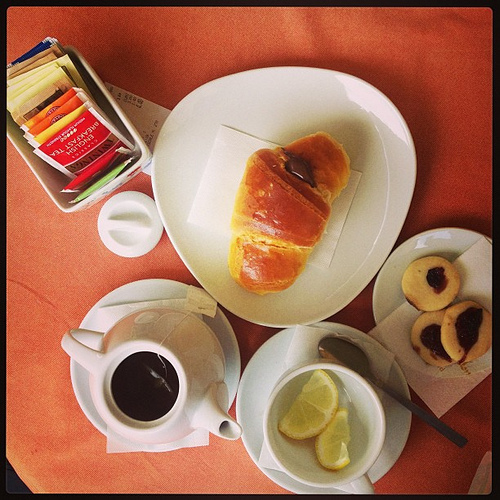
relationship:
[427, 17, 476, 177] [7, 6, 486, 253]
table cloth on table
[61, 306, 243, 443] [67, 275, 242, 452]
kettle on plate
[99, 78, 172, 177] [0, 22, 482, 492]
bill on table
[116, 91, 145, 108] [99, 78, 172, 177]
black lettering on bill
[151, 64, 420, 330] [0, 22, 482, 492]
plate on table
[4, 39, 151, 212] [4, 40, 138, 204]
container holding bags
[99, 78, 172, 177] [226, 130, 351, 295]
bill on crossant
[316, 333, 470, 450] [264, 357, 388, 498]
metal spoon on cup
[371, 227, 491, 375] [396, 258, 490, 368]
plate on cookies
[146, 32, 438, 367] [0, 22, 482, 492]
plate on table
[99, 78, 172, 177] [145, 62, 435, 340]
bill on plate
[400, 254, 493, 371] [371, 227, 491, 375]
cookies on plate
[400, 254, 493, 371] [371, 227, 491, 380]
cookies on plate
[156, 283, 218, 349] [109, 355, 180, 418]
bag string on brewed drink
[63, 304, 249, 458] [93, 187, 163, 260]
kettle on top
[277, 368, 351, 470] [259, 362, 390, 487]
lemon in cup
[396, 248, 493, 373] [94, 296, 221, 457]
cookies on napkin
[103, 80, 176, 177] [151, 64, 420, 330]
bill beneath plate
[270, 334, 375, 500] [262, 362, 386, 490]
lemon in bowel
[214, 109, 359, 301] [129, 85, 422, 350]
crossant on plate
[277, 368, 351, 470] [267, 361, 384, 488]
lemon in bowel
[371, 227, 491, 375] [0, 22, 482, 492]
plate on table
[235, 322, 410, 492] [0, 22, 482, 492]
plate on table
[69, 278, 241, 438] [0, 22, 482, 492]
plate on table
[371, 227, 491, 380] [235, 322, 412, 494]
plate on plate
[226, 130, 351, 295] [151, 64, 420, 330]
crossant on plate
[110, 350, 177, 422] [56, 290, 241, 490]
drink in kettle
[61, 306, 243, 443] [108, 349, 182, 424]
kettle full of brewed drink